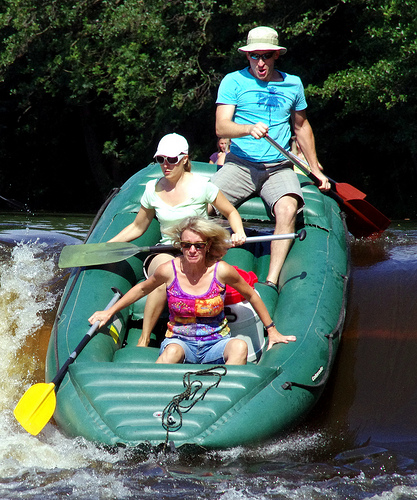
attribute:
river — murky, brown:
[21, 441, 416, 500]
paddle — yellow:
[16, 377, 62, 436]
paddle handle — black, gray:
[57, 302, 105, 386]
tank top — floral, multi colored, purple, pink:
[160, 259, 232, 328]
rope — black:
[162, 371, 223, 439]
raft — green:
[52, 163, 348, 457]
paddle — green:
[53, 236, 148, 273]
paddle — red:
[335, 194, 393, 241]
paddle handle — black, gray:
[269, 139, 331, 198]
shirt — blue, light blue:
[218, 66, 311, 171]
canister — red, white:
[218, 265, 280, 349]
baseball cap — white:
[153, 128, 190, 164]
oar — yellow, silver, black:
[12, 297, 103, 435]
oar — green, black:
[56, 236, 182, 266]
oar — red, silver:
[262, 128, 396, 247]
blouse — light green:
[139, 178, 223, 233]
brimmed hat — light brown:
[233, 20, 290, 53]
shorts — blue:
[212, 154, 309, 204]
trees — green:
[6, 8, 412, 160]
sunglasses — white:
[155, 154, 184, 164]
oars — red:
[313, 157, 396, 254]